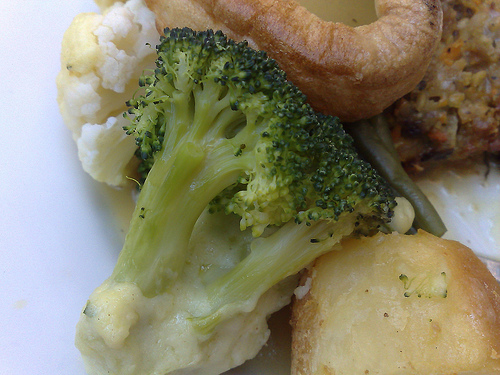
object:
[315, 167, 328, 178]
green speckle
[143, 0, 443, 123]
food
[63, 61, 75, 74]
speck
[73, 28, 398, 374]
broccoli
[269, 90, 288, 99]
green speckle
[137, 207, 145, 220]
green spot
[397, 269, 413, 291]
speck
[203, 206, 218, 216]
speckle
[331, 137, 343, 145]
speckle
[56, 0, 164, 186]
cauliflower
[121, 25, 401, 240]
cauliflower head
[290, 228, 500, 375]
food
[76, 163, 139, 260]
shadow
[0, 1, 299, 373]
plate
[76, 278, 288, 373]
white sauce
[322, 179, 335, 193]
speckle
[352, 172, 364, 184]
speckle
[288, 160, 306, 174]
speckle